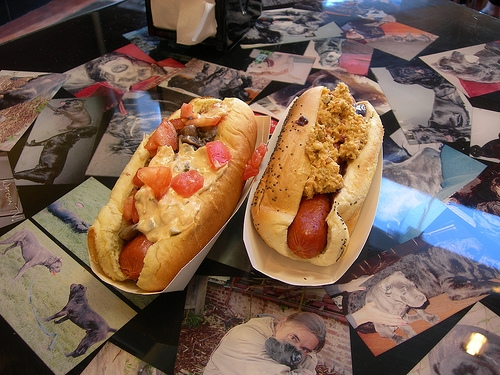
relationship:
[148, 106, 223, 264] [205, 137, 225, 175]
hotdog with tomato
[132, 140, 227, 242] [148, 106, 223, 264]
melted cheese on hotdog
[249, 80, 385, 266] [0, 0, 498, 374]
hotdog on top of table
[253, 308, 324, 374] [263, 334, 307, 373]
man holding dog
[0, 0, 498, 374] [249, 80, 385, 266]
table with two hotdog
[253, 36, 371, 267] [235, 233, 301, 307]
hotdog in holder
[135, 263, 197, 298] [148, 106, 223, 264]
tray holding hotdog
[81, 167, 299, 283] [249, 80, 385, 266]
trays with hotdog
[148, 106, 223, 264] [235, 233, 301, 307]
hotdog on holder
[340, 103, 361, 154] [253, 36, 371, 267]
sauce on hotdog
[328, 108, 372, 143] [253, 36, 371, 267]
mustard on hotdog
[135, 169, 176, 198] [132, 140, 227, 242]
tomatoe on melted cheese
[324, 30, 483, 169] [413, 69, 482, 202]
pictures of dogs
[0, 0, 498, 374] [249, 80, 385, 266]
table with hotdog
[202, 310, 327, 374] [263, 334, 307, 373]
man with dog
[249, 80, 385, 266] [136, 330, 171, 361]
hotdog on top of glass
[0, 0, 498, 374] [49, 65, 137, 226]
table covered in photos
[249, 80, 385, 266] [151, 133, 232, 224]
hotdog with condiments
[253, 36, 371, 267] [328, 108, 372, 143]
hotdog with mustard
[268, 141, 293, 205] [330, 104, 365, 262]
black seeds on bun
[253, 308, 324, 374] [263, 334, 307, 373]
man hugging dog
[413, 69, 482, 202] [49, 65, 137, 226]
dogs in photos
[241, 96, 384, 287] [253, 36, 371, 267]
trays for hotdog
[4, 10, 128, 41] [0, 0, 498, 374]
table in table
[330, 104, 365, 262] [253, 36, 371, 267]
bun of hotdog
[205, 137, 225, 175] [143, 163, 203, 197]
tomato that has been cut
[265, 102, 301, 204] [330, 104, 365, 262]
seeds on bun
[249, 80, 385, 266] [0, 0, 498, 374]
hotdog sitting on table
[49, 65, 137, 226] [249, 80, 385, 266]
photos under hotdog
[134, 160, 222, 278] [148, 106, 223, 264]
melted cheese on hotdog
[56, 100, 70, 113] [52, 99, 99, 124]
tounge hanging out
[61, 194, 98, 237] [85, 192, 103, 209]
dog lying in grass